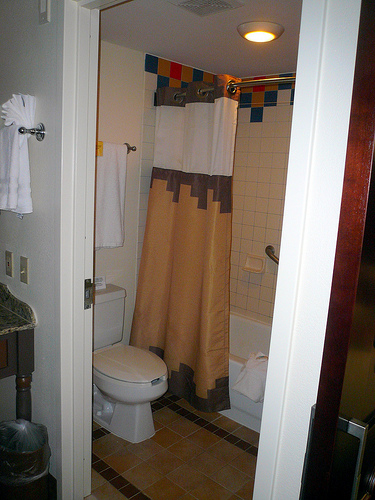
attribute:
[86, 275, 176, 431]
toilet — white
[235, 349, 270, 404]
wash rag — white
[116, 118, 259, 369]
curtain — white, brown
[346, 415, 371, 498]
door knob — long, silver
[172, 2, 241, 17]
vent — square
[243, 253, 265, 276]
dish — empty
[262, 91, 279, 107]
tile — yellow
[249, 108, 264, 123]
tile — red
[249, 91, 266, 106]
tile — blue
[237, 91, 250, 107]
tile — yellow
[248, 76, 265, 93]
tile — yellow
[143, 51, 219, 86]
tile border — colorful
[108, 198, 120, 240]
towel — white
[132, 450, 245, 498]
floor — yellow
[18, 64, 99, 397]
wall — white